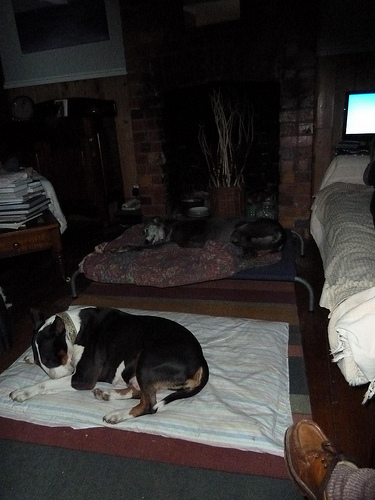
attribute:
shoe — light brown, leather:
[283, 418, 343, 498]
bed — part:
[309, 157, 373, 403]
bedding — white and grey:
[310, 181, 373, 402]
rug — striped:
[208, 275, 313, 374]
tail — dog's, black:
[156, 363, 216, 411]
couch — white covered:
[285, 145, 373, 412]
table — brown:
[185, 273, 261, 300]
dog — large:
[13, 297, 234, 444]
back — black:
[121, 311, 199, 345]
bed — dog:
[0, 304, 294, 456]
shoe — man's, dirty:
[281, 417, 349, 497]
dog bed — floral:
[81, 219, 283, 288]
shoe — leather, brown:
[279, 417, 337, 486]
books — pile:
[0, 152, 69, 233]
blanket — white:
[222, 310, 287, 445]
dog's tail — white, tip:
[150, 357, 213, 411]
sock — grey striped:
[329, 464, 371, 498]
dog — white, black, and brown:
[11, 303, 217, 420]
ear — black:
[48, 309, 68, 333]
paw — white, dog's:
[11, 380, 32, 403]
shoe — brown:
[281, 417, 345, 492]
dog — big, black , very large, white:
[100, 212, 295, 259]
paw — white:
[12, 381, 33, 400]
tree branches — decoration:
[199, 97, 249, 187]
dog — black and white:
[8, 309, 208, 425]